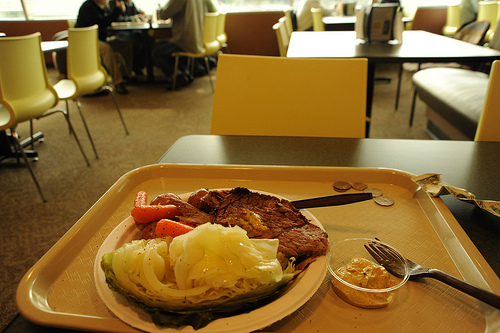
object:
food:
[154, 217, 194, 239]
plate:
[90, 187, 334, 332]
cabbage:
[99, 221, 301, 331]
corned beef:
[165, 186, 331, 272]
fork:
[363, 236, 500, 310]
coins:
[372, 195, 394, 207]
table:
[0, 132, 500, 333]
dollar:
[410, 172, 500, 220]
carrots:
[129, 204, 183, 225]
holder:
[362, 6, 375, 45]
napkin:
[354, 7, 364, 40]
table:
[104, 20, 173, 86]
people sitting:
[146, 0, 220, 92]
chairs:
[0, 31, 95, 204]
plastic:
[0, 31, 61, 132]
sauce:
[329, 257, 395, 311]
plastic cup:
[324, 236, 413, 310]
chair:
[209, 53, 369, 139]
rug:
[1, 136, 143, 166]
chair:
[50, 23, 130, 160]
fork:
[290, 192, 373, 209]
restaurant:
[2, 1, 500, 331]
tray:
[11, 161, 500, 333]